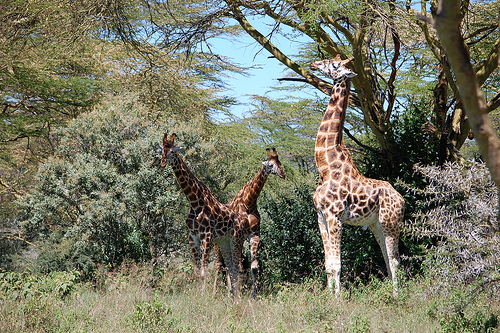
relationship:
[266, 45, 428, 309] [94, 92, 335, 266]
giraffe are outside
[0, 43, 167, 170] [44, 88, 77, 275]
trees in distance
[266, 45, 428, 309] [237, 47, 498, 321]
giraffe in wild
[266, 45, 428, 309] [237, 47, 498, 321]
giraffe in photo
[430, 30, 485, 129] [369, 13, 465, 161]
trunk of tree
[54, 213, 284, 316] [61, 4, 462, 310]
vegetation in picture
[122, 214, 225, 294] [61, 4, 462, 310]
shrubs in picture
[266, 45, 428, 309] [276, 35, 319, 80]
giraffe feeding leaves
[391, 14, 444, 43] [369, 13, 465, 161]
nest on tree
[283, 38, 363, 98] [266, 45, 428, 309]
head of giraffe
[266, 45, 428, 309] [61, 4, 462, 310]
giraffe in forest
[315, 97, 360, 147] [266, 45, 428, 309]
neck of giraffe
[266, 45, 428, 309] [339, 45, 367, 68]
giraffe has horns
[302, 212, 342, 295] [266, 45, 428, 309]
leg of giraffe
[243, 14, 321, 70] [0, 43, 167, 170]
branches of trees